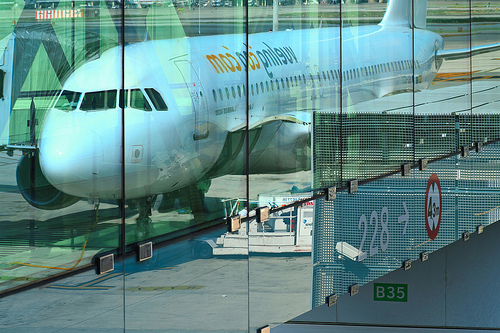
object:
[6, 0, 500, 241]
airplane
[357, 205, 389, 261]
228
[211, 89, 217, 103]
windows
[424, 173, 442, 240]
sign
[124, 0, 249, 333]
windows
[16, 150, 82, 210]
engine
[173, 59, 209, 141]
door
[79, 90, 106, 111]
windshield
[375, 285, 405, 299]
b35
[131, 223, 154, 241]
wheel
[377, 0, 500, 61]
tail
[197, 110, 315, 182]
wing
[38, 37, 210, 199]
cockpit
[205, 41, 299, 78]
name